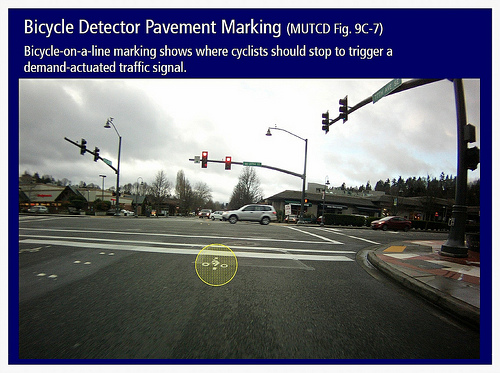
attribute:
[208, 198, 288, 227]
suv — silver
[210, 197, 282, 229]
suv — silver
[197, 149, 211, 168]
traffic light — lit up, red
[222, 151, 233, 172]
traffic light — lit up, red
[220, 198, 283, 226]
suv — silver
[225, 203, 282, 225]
suv — silver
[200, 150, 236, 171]
lights — red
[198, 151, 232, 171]
lights — red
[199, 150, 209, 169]
light — red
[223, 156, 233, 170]
light — red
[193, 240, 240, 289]
circle — yellow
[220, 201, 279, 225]
vehicle — silver, SUV type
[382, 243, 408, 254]
spot — orange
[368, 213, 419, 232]
vehicle — red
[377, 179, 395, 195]
leaves — green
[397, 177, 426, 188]
leaves — green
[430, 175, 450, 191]
leaves — green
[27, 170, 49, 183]
leaves — green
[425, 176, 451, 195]
leaves — green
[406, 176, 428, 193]
leaves — green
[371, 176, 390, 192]
leaves — green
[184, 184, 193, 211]
leaves — green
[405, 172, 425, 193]
leaves — green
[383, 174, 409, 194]
leaves — green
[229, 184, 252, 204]
leaves — green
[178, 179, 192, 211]
leaves — green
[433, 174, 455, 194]
leaves — green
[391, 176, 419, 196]
leaves — green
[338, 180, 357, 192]
leaves — green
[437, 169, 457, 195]
leaves — green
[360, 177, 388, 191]
leaves — green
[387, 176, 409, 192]
leaves — green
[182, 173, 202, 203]
leaves — green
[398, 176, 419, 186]
leaves — green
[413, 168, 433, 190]
leaves — green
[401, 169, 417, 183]
leaves — green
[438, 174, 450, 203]
leaves — green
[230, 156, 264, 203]
leaves — green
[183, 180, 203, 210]
leaves — green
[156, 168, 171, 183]
leaves — green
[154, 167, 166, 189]
leaves — green